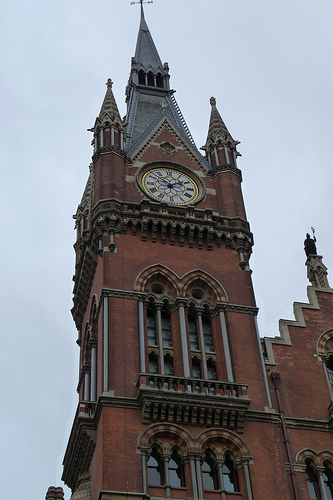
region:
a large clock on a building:
[133, 156, 210, 214]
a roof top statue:
[293, 224, 324, 259]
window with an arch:
[130, 419, 195, 497]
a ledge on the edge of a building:
[128, 368, 259, 436]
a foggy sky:
[2, 229, 60, 430]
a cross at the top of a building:
[128, 0, 157, 18]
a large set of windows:
[131, 259, 240, 398]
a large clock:
[133, 157, 208, 212]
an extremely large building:
[42, 0, 329, 496]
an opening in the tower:
[135, 67, 147, 86]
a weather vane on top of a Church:
[130, 0, 156, 20]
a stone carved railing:
[139, 369, 248, 427]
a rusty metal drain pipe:
[272, 382, 299, 497]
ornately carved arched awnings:
[142, 424, 247, 463]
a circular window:
[150, 279, 163, 295]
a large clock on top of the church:
[133, 162, 204, 206]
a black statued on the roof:
[293, 217, 319, 255]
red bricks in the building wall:
[259, 438, 279, 494]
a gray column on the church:
[101, 296, 112, 393]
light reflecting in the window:
[220, 471, 239, 490]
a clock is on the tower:
[133, 159, 209, 207]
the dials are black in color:
[155, 173, 182, 187]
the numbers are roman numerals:
[148, 169, 195, 205]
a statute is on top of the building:
[301, 231, 320, 258]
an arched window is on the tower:
[138, 419, 193, 497]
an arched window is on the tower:
[197, 424, 256, 499]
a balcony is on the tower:
[137, 371, 250, 426]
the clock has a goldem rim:
[142, 165, 201, 211]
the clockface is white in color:
[145, 165, 197, 211]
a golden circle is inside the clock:
[154, 174, 186, 196]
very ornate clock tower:
[57, 0, 254, 493]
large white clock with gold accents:
[134, 157, 209, 214]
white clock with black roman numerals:
[134, 162, 213, 202]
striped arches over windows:
[132, 420, 259, 466]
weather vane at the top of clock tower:
[123, 0, 161, 34]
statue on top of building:
[298, 218, 322, 265]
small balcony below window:
[137, 368, 252, 425]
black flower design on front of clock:
[157, 173, 186, 192]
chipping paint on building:
[267, 306, 332, 370]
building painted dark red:
[96, 290, 143, 483]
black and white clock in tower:
[133, 149, 195, 214]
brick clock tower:
[73, 15, 279, 455]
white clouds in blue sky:
[27, 58, 70, 121]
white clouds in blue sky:
[16, 233, 35, 268]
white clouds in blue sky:
[36, 342, 58, 381]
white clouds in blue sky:
[207, 25, 231, 50]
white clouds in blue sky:
[281, 106, 303, 150]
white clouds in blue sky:
[193, 9, 265, 61]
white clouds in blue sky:
[22, 40, 71, 83]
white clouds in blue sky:
[31, 163, 53, 202]